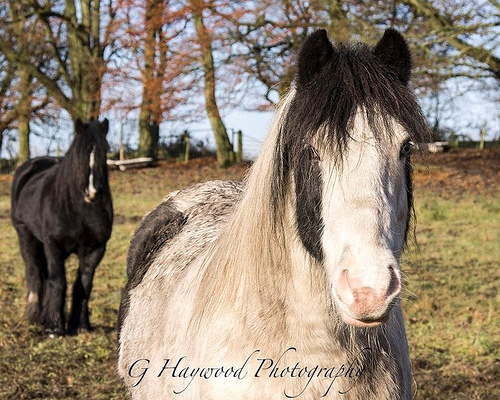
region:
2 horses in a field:
[10, 10, 485, 387]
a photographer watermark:
[119, 349, 381, 390]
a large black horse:
[22, 127, 113, 336]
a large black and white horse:
[140, 53, 457, 380]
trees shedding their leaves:
[93, 12, 267, 135]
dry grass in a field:
[442, 210, 499, 333]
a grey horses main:
[235, 159, 314, 304]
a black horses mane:
[55, 142, 85, 215]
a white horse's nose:
[322, 250, 434, 353]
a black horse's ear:
[290, 30, 349, 91]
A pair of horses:
[11, 40, 408, 398]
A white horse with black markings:
[119, 46, 422, 387]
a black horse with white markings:
[18, 123, 113, 324]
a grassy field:
[17, 166, 499, 387]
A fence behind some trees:
[47, 125, 241, 170]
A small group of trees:
[11, 4, 224, 156]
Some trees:
[235, 0, 490, 133]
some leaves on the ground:
[403, 145, 498, 205]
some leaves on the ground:
[0, 129, 245, 201]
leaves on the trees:
[100, 12, 262, 109]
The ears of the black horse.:
[71, 112, 115, 137]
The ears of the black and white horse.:
[287, 27, 409, 73]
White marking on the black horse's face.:
[82, 146, 103, 193]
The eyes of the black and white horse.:
[301, 126, 418, 168]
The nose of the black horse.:
[80, 188, 104, 208]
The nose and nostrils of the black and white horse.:
[339, 255, 404, 312]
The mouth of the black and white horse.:
[340, 308, 392, 333]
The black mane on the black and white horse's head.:
[304, 42, 418, 131]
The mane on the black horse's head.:
[69, 116, 107, 156]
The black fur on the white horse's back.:
[111, 190, 193, 316]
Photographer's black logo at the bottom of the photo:
[121, 345, 386, 397]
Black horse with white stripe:
[2, 105, 116, 337]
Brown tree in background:
[175, 2, 246, 176]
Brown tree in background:
[132, 3, 168, 160]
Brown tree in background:
[4, 0, 48, 166]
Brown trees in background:
[57, 7, 117, 149]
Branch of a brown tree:
[404, 1, 498, 74]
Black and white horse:
[117, 32, 442, 397]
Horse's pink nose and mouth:
[323, 262, 404, 326]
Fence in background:
[113, 123, 252, 173]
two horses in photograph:
[22, 28, 489, 393]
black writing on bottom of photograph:
[118, 352, 370, 389]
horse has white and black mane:
[201, 58, 422, 326]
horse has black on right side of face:
[255, 100, 346, 298]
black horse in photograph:
[6, 85, 126, 346]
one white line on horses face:
[76, 137, 109, 210]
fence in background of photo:
[13, 116, 263, 159]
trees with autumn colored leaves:
[10, 10, 265, 127]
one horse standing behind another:
[20, 50, 477, 375]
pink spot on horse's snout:
[341, 240, 402, 325]